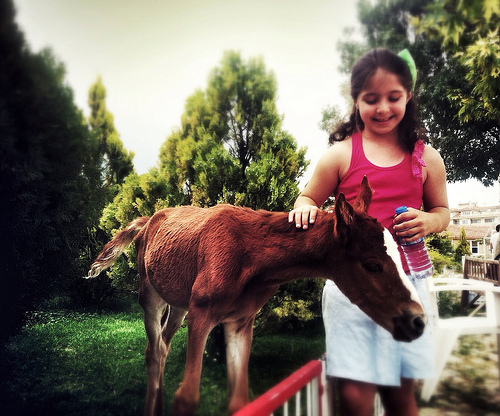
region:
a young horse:
[95, 201, 426, 409]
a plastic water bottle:
[393, 205, 430, 278]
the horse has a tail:
[88, 215, 141, 278]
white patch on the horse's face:
[381, 226, 421, 308]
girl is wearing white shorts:
[320, 271, 436, 386]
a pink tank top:
[339, 131, 433, 267]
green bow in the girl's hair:
[397, 48, 418, 95]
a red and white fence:
[231, 363, 326, 415]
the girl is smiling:
[346, 64, 416, 134]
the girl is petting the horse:
[281, 43, 442, 414]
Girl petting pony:
[276, 36, 478, 414]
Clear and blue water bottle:
[390, 201, 439, 281]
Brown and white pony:
[82, 171, 429, 414]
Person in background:
[478, 218, 498, 264]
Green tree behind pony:
[75, 40, 336, 320]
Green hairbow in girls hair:
[386, 44, 421, 94]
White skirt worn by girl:
[316, 275, 450, 388]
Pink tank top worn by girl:
[336, 130, 437, 270]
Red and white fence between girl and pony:
[220, 336, 416, 414]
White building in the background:
[438, 188, 499, 224]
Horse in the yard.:
[66, 124, 398, 410]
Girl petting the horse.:
[288, 42, 476, 370]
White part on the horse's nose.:
[371, 218, 449, 344]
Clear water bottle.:
[373, 176, 465, 305]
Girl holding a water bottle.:
[263, 46, 494, 415]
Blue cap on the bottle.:
[374, 196, 421, 228]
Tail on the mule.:
[51, 161, 173, 296]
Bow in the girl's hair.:
[338, 40, 425, 136]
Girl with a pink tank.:
[328, 110, 480, 267]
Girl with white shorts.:
[283, 218, 432, 405]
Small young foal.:
[72, 204, 422, 414]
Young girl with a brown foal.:
[73, 43, 480, 410]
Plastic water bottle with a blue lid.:
[385, 202, 443, 304]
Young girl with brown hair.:
[341, 38, 426, 160]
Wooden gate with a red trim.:
[230, 350, 332, 413]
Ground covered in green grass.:
[25, 312, 137, 405]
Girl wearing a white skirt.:
[303, 28, 460, 390]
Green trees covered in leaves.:
[115, 45, 312, 206]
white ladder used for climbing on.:
[417, 261, 498, 408]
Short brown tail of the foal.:
[70, 206, 152, 292]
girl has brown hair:
[347, 58, 405, 118]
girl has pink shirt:
[340, 110, 410, 295]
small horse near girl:
[147, 178, 423, 381]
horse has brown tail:
[102, 206, 173, 281]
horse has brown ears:
[333, 183, 368, 243]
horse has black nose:
[388, 278, 418, 338]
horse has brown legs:
[140, 306, 252, 381]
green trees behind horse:
[85, 74, 275, 235]